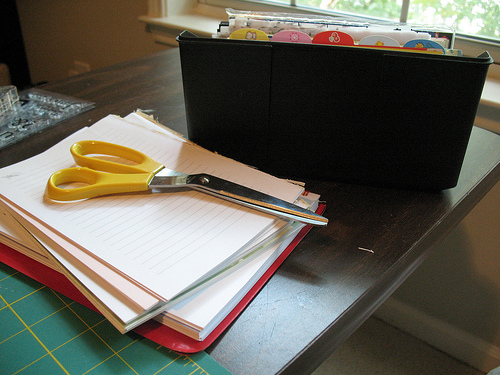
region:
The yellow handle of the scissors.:
[55, 128, 152, 215]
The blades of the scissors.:
[152, 156, 339, 247]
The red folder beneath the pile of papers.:
[2, 233, 312, 355]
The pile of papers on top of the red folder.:
[10, 148, 318, 315]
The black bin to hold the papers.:
[176, 25, 476, 197]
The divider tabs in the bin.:
[226, 21, 439, 63]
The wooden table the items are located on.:
[22, 25, 499, 374]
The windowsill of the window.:
[157, 11, 497, 126]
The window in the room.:
[209, 6, 499, 38]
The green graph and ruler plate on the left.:
[3, 258, 215, 373]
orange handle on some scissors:
[44, 164, 152, 204]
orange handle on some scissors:
[64, 135, 164, 175]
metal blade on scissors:
[165, 164, 328, 277]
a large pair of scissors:
[41, 133, 336, 238]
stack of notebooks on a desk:
[2, 100, 331, 348]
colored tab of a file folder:
[226, 28, 269, 40]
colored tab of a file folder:
[267, 28, 314, 43]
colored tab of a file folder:
[310, 30, 353, 47]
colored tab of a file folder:
[352, 34, 404, 51]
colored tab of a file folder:
[398, 37, 447, 54]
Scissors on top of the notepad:
[81, 117, 329, 237]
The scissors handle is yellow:
[60, 110, 145, 205]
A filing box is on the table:
[186, 9, 498, 187]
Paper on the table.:
[83, 47, 303, 308]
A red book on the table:
[37, 272, 252, 364]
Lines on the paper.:
[109, 191, 224, 251]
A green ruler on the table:
[11, 306, 110, 373]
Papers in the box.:
[244, 3, 434, 56]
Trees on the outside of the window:
[347, 4, 479, 33]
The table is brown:
[73, 59, 165, 111]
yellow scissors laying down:
[39, 133, 327, 233]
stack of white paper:
[0, 102, 328, 349]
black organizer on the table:
[160, 16, 497, 207]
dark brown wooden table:
[4, 33, 497, 374]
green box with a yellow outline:
[22, 306, 96, 351]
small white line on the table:
[354, 240, 382, 257]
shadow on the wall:
[416, 243, 498, 320]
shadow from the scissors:
[284, 256, 324, 289]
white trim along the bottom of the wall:
[374, 293, 499, 369]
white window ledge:
[144, 11, 497, 118]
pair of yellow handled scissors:
[62, 108, 335, 262]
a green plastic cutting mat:
[5, 305, 90, 371]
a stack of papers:
[2, 106, 321, 355]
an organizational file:
[172, 1, 492, 203]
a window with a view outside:
[390, 1, 499, 52]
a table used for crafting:
[357, 198, 412, 253]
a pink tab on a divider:
[273, 28, 314, 50]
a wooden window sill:
[139, 6, 199, 41]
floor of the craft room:
[375, 333, 436, 374]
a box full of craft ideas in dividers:
[157, 1, 494, 206]